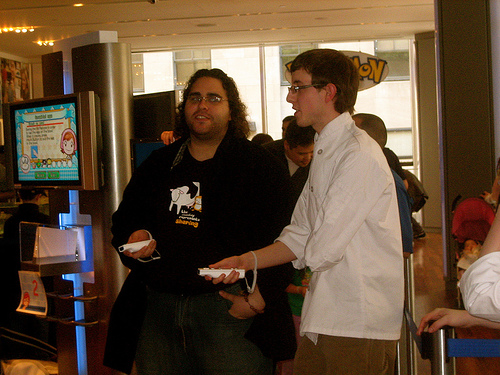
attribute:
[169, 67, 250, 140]
hair — long, longish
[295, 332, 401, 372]
pants — brown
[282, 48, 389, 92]
sticker — partial, pokemon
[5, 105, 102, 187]
television — turned on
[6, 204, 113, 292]
wii — white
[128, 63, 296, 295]
man — dressed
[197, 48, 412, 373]
chef jacket — white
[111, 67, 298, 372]
guy — playing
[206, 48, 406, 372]
guy — playing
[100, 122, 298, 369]
clothing — black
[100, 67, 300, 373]
man — brown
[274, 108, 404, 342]
shirt — white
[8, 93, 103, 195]
tv — flat